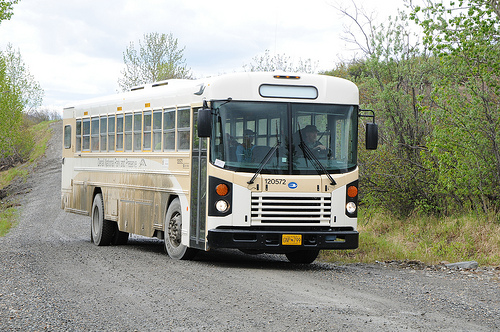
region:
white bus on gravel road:
[62, 70, 382, 265]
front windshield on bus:
[210, 98, 359, 172]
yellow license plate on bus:
[283, 233, 302, 243]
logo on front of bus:
[288, 182, 296, 187]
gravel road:
[1, 118, 498, 330]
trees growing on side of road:
[355, 0, 499, 216]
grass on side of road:
[309, 203, 498, 273]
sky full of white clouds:
[0, 1, 497, 118]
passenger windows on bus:
[73, 106, 191, 155]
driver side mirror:
[358, 108, 379, 152]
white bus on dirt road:
[52, 63, 371, 277]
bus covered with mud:
[52, 68, 374, 273]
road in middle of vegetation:
[2, 3, 489, 319]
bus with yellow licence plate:
[197, 60, 369, 263]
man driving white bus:
[57, 77, 371, 264]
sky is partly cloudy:
[3, 0, 498, 77]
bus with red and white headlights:
[200, 60, 365, 274]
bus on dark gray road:
[11, 65, 443, 305]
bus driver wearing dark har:
[289, 115, 343, 167]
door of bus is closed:
[158, 78, 239, 265]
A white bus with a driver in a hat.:
[61, 71, 378, 261]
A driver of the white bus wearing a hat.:
[296, 121, 328, 162]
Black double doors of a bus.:
[187, 105, 211, 247]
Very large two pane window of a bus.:
[208, 99, 358, 174]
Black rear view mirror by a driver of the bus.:
[356, 107, 379, 149]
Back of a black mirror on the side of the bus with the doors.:
[195, 103, 216, 139]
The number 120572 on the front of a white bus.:
[263, 177, 288, 189]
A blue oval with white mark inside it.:
[286, 180, 298, 188]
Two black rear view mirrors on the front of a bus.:
[198, 100, 378, 152]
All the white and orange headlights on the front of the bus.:
[215, 182, 356, 216]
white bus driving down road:
[52, 68, 372, 263]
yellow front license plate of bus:
[281, 228, 301, 245]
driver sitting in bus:
[295, 118, 326, 160]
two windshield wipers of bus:
[241, 123, 341, 189]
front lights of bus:
[213, 178, 358, 219]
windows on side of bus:
[61, 113, 192, 152]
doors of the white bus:
[183, 113, 211, 244]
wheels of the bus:
[84, 190, 186, 252]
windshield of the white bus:
[216, 106, 357, 168]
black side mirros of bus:
[191, 96, 379, 154]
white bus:
[69, 66, 351, 264]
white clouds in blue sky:
[34, 13, 97, 41]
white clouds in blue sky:
[30, 39, 79, 62]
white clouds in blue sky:
[78, 24, 114, 65]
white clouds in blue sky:
[27, 48, 73, 86]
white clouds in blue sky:
[110, 4, 192, 29]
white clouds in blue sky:
[194, 7, 238, 67]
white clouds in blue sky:
[219, 15, 253, 62]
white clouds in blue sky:
[245, 7, 279, 57]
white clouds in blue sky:
[267, 13, 305, 46]